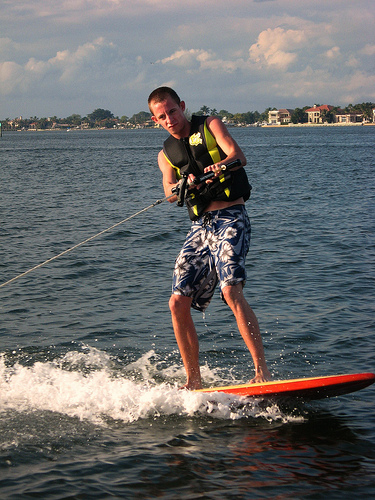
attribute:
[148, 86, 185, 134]
head — man's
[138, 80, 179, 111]
hair — brown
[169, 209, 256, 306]
shorts — blue, white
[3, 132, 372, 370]
water — clear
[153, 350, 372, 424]
wakeboard — orange, yellow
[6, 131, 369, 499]
water — white, bubbling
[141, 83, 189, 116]
hair — short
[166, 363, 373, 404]
board — white, orange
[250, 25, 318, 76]
cloud — large, white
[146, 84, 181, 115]
hair — short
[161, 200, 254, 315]
shorts — white, blue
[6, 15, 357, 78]
clouds — dark, thick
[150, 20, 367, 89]
clouds — puffy, thick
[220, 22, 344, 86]
clouds — many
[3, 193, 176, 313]
cord — grey